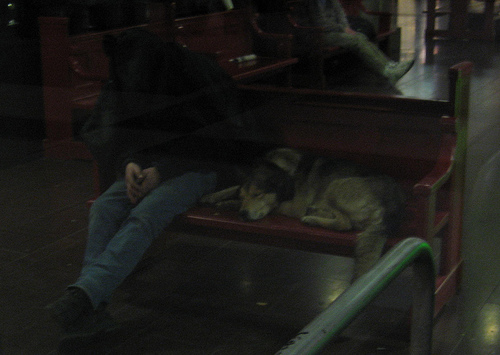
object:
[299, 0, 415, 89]
person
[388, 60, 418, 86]
shoes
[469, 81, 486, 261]
floor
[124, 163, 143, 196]
hands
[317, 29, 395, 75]
pants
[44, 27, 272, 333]
man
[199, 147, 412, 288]
dog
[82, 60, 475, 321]
seat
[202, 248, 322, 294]
black tile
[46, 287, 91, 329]
black shoes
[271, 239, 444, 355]
railing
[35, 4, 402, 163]
bench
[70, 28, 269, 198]
black jacket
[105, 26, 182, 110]
head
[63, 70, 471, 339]
bench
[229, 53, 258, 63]
magazine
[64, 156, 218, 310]
jeans